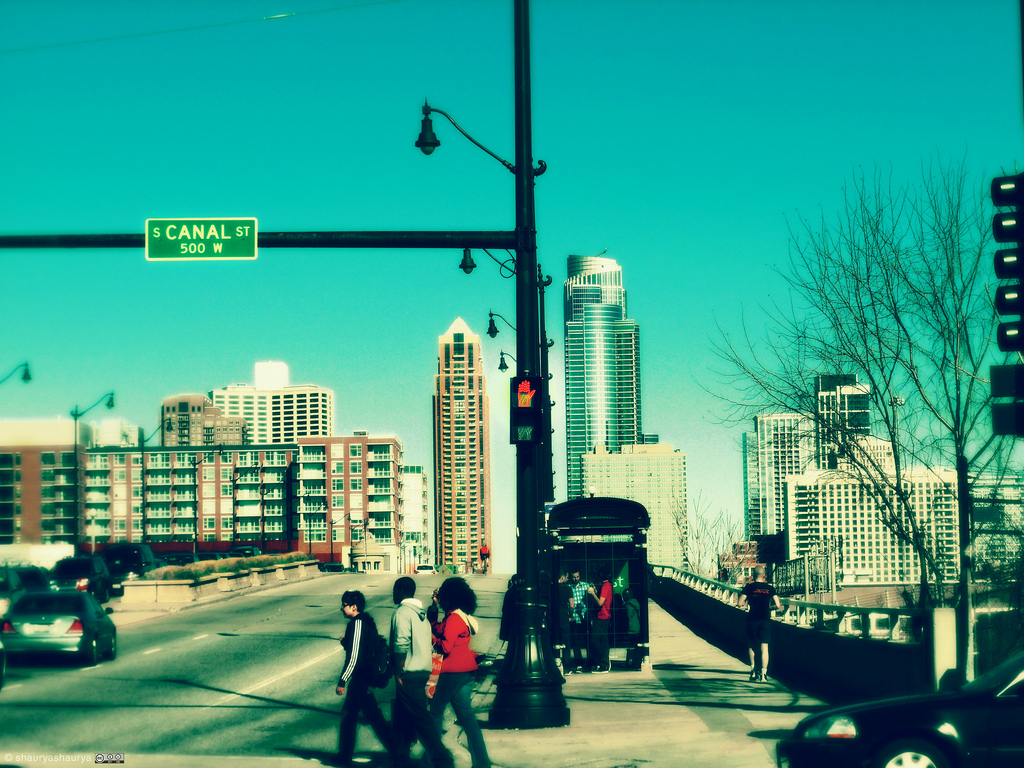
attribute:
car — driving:
[4, 571, 132, 664]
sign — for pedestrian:
[510, 372, 537, 407]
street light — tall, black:
[406, 100, 573, 731]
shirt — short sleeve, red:
[589, 584, 618, 619]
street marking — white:
[181, 629, 220, 647]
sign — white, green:
[144, 204, 261, 259]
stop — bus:
[549, 484, 660, 685]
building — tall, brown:
[426, 310, 494, 576]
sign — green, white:
[104, 180, 338, 375]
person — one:
[584, 567, 615, 674]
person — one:
[564, 563, 595, 676]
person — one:
[539, 567, 576, 671]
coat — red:
[430, 603, 502, 677]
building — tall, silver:
[526, 236, 682, 552]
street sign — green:
[141, 212, 260, 264]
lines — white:
[158, 631, 293, 725]